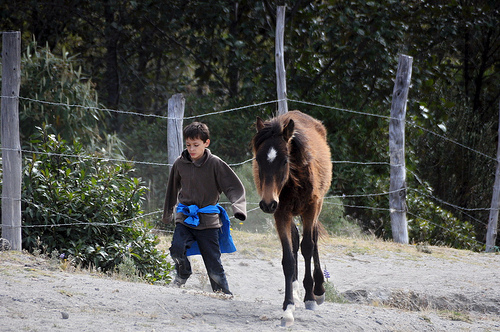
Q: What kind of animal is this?
A: Horse.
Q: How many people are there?
A: 1.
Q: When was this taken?
A: Daytime.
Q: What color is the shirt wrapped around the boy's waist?
A: Blue.